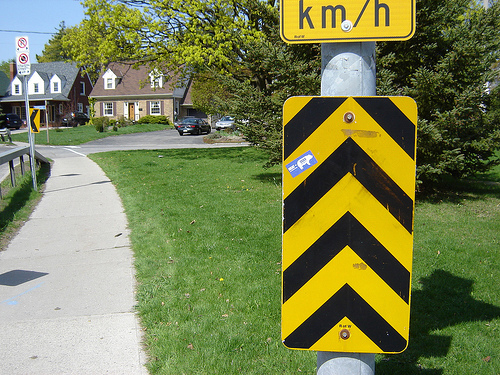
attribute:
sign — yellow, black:
[281, 96, 418, 354]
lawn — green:
[6, 123, 173, 146]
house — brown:
[89, 60, 220, 126]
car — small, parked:
[176, 117, 212, 137]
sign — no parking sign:
[15, 35, 31, 51]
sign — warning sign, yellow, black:
[28, 107, 42, 135]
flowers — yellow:
[58, 1, 278, 83]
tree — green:
[58, 1, 279, 96]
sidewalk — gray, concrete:
[1, 156, 146, 374]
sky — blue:
[0, 1, 258, 65]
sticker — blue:
[284, 150, 318, 179]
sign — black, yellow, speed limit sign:
[277, 1, 417, 45]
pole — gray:
[318, 41, 378, 95]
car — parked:
[58, 111, 89, 128]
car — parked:
[215, 115, 250, 130]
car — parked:
[3, 112, 24, 129]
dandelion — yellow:
[219, 277, 225, 283]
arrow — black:
[30, 109, 38, 132]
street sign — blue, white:
[33, 104, 45, 111]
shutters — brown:
[145, 100, 166, 117]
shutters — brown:
[98, 101, 118, 119]